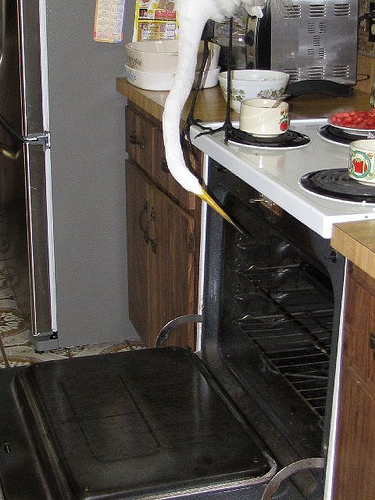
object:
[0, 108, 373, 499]
oven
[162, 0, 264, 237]
bird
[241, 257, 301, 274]
racks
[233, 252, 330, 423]
grate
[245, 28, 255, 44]
knobs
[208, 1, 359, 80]
toaster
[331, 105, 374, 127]
red food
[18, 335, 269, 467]
window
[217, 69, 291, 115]
bowl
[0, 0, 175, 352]
refrigerator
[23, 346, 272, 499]
door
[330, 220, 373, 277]
countertop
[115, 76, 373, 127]
countertop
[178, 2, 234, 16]
feather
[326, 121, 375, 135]
plate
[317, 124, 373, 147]
burner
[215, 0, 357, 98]
oven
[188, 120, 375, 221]
counter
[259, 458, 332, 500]
hinge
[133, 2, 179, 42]
stickers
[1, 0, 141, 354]
fridge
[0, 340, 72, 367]
tile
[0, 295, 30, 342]
tile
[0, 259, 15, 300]
tile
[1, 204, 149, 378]
floor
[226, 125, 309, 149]
burner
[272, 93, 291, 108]
utensil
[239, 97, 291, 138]
bowl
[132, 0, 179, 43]
yellow papers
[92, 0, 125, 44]
yellow papers